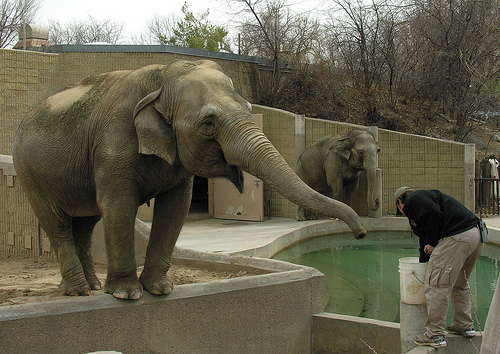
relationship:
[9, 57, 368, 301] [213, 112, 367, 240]
elephant extending trunk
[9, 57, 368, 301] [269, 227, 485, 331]
elephant standing next to pool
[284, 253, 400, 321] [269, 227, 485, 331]
stairs built into pool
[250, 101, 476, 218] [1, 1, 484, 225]
wall standing in background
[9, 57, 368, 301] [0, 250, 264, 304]
elephant standing in dirt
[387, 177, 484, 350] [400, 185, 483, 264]
man wearing sweatshirt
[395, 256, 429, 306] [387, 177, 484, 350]
bucket standing next to man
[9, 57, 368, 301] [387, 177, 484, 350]
elephant standing next to man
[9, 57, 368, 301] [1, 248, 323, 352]
elephant standing on ledge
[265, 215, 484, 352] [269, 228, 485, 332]
pool containing water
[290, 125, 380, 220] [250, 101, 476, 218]
elephant standing next to wall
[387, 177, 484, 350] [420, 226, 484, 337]
man wearing pants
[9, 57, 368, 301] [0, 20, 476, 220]
elephant standing in front of building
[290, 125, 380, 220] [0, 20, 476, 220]
elephant standing in front of building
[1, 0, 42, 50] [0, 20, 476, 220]
tree standing behind building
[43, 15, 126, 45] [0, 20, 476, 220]
tree standing behind building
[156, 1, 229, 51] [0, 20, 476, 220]
tree standing behind building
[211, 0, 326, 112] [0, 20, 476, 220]
tree standing behind building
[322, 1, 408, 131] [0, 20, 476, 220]
tree standing behind building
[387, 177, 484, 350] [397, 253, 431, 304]
man digging in bucket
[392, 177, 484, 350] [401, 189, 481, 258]
man wearing jacket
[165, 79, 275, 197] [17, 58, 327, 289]
face of an elephant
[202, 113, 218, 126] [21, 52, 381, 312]
right eye of an elephant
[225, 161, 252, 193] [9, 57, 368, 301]
mouth of an elephant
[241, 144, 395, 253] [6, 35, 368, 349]
trunk of an elephant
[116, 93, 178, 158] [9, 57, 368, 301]
ear of an elephant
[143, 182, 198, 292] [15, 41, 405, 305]
left leg of an elephant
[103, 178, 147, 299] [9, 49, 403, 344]
front legs of an elephant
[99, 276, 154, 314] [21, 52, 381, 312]
toes of an elephant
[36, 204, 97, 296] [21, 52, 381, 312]
back legs of an elephant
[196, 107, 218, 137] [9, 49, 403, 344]
right eye of elephant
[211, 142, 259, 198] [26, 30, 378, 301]
mouth of elephant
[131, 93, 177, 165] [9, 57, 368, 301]
ear of elephant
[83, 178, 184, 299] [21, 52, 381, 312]
front legs of elephant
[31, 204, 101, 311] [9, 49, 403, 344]
back legs of elephant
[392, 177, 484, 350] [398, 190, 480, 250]
man wearing black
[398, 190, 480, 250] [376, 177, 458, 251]
black on man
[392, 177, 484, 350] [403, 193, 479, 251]
man wearing jacket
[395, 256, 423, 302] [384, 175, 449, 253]
bucket near man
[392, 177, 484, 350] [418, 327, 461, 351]
man wearing sneakers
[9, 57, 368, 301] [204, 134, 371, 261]
elephant holding her trunk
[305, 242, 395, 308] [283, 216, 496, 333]
water in pool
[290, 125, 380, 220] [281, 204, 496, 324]
elephant standing by pool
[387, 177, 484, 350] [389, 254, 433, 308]
man reaching into bucket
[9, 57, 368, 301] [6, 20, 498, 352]
elephant at zoo